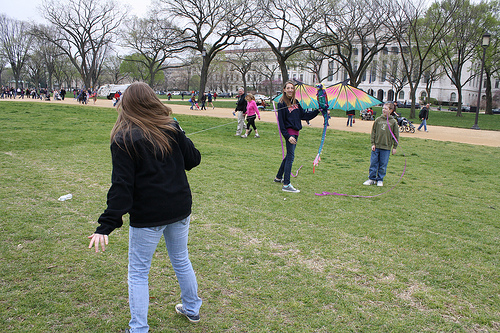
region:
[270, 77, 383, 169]
kite shaped like a dragon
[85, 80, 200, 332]
girl holding kite string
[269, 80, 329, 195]
girl holding kite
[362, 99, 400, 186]
boy standing next to kite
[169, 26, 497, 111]
large white building in the background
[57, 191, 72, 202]
plastic bottle on the grass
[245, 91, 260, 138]
woman wearing pink jacket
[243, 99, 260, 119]
pink jacket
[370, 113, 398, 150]
olive green sweatshirt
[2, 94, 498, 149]
walking path in background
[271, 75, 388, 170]
rainbow dragon kite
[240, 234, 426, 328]
patches of dry grass in lawn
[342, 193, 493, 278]
short green grassy lawn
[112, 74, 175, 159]
woman with brown hair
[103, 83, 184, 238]
woman wearing black jacket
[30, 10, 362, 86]
trees with no leaves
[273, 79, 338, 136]
woman holding dragon kite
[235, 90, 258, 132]
woman wearing pink jacket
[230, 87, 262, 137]
two people walking on grass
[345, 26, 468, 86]
white building behind trees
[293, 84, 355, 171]
big colorful dragonfly kite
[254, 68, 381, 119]
Very colorful bird kite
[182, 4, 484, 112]
Old white historical building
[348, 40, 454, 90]
Greek style white columns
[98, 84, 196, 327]
Woman holding kite string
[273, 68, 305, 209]
Woman holding kite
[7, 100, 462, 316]
Large green grass park area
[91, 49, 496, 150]
Dirt walking park trail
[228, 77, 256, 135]
Older couple holding hands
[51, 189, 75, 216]
Litter on park ground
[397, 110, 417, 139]
Baby jogging stroller on path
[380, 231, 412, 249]
grass on the ground.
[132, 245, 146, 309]
jeans on girl's leg.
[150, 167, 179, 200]
black sweater on girl.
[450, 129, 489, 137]
path near the grass.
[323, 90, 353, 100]
kite in girl's hand.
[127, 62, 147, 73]
leaves on the tree.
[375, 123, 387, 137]
green sweatshirt on boy.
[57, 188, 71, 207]
bottle on the ground.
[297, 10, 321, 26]
bare limbs on tree.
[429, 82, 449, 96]
white building behind trees.